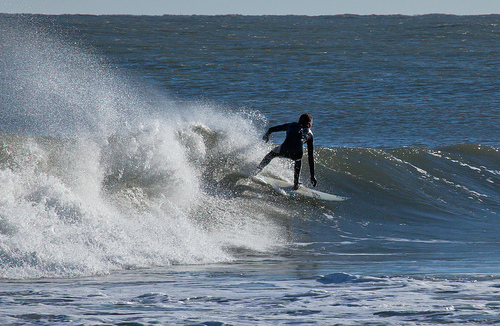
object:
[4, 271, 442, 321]
waves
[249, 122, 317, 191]
wetsuit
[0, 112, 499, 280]
waves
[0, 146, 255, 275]
water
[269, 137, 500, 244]
waves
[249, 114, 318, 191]
person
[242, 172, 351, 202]
surfboard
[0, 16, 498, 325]
ocean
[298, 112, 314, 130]
head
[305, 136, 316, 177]
arm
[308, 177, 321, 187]
hand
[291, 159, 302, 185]
leg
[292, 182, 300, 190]
foot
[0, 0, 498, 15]
sky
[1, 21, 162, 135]
splash